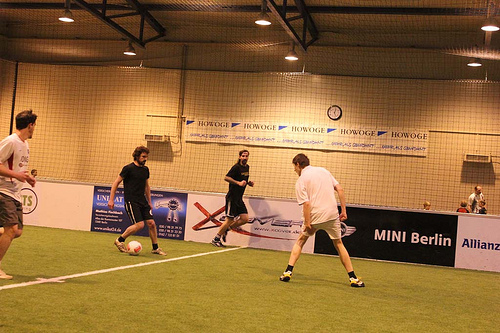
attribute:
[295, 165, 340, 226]
shirt — white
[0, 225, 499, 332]
court — green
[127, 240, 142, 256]
ball — red, white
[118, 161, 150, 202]
shirt — black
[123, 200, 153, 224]
shorts — black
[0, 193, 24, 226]
shorts — brown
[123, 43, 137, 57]
light — hanging down, suspended, overhead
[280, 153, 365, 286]
person — playing, male, soccer player, indoor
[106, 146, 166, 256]
person — playing, running, indoor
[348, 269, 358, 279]
sock — black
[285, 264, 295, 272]
sock — black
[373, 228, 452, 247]
text — white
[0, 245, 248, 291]
line — white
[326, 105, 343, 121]
clock — indoor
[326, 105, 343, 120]
frame — black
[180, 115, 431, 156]
banner — white, blue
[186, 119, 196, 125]
triangle — blue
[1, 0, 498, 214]
net — protective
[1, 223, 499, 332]
turf — artificial, indoor